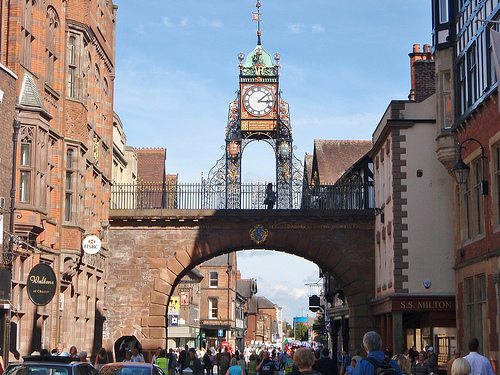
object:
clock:
[241, 83, 278, 119]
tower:
[223, 0, 295, 208]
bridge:
[108, 196, 375, 254]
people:
[43, 331, 496, 374]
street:
[0, 320, 500, 375]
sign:
[25, 263, 58, 307]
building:
[0, 0, 118, 375]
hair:
[362, 330, 383, 351]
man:
[461, 337, 496, 375]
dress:
[461, 352, 496, 374]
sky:
[110, 0, 436, 206]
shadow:
[190, 208, 500, 375]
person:
[262, 182, 280, 210]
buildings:
[303, 0, 500, 375]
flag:
[252, 13, 259, 21]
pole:
[256, 2, 261, 45]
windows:
[65, 146, 73, 222]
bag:
[374, 364, 397, 375]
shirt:
[353, 352, 404, 375]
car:
[100, 362, 166, 375]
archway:
[227, 102, 293, 210]